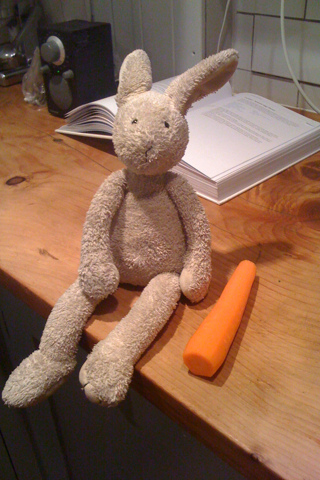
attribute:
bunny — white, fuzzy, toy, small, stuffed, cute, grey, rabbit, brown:
[27, 35, 225, 392]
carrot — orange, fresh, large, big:
[186, 260, 268, 381]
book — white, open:
[74, 68, 307, 195]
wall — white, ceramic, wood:
[182, 3, 317, 69]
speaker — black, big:
[34, 19, 117, 106]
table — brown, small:
[7, 112, 315, 374]